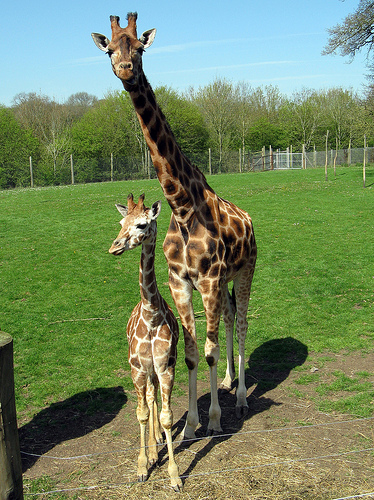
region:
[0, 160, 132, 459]
giraffe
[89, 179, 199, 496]
brown and tan spotted giraffe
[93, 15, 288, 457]
brown and tan spotted giraffe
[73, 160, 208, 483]
baby brown and tan spotted giraffe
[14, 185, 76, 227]
short green and brown grass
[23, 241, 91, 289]
short green and brown grass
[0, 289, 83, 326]
short green and brown grass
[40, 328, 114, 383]
short green and brown grass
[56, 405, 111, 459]
short green and brown grass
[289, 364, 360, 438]
short green and brown grass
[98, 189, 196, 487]
baby giraffe standing behind wire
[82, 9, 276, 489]
adult and baby giraffe standing together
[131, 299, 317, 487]
shadows from the giraffes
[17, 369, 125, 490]
shadow on ground beside giraffes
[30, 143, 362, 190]
fence along back of enclosure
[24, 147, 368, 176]
wooden posts of fencing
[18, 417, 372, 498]
wire line of fence in foreground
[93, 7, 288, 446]
giraffe looking directly at camera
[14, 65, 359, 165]
trees along fence line in background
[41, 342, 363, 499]
patch of dirt giraffes are standing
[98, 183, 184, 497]
This is a giraffe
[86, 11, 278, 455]
This is a giraffe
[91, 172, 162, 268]
Head of a giraffe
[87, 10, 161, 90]
Head of a giraffe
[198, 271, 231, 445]
Leg of a giraffe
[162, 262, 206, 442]
Leg of a giraffe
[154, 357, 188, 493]
Leg of a giraffe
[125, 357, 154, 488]
Leg of a giraffe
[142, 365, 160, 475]
Leg of a giraffe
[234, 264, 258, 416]
Leg of a giraffe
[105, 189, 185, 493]
Baby giraffe in front of large giraffe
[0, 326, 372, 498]
Fence in front of giraffes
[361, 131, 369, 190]
Wood pole stuck on grass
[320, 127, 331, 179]
Wood pole stuck on grass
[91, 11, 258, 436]
Giraffe inside giraffe pen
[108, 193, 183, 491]
Giraffe inside giraffe pen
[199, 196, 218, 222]
Large brown spot on giraffe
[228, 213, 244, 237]
Large brown spot on giraffe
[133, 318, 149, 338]
Large brown spot on giraffe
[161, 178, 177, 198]
Large brown spot on giraffe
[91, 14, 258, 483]
pair of giraffes in the sun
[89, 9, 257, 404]
baby giraffe with its mother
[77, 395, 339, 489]
bare patchy ground with old dead grass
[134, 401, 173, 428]
front knees of a giraffe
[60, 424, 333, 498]
modest wire fencing lining pen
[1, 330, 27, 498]
thick wooden post for wire fencing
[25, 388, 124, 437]
shadow cast from fence post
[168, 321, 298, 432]
shadows cast from two giraffes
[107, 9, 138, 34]
uneven and fuzzy tips anters of mother giraffe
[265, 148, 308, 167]
gated entrance to animal pen